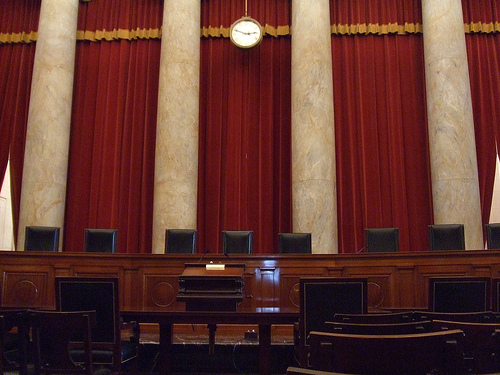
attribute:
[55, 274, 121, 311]
chair — black, wooden, empty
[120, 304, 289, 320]
desk — large, long, wooden, brown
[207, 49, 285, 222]
curtain — red, big, long, large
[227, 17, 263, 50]
clock — white, high, small, hanging, brown, round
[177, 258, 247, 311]
podium — wooden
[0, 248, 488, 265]
desk — long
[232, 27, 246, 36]
clock hand — black, dark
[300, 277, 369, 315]
chair — black, wooden, dark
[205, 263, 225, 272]
paper — white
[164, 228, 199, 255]
seat — black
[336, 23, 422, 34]
curtain — yellow, gold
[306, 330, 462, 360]
seat — brown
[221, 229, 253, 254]
chair — tall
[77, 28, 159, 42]
trim — gold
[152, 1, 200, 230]
pillar — grey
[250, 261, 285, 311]
reflection — bright